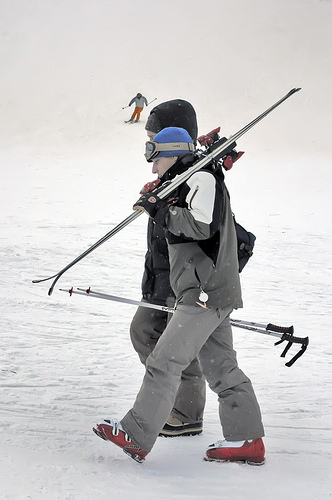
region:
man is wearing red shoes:
[99, 419, 145, 463]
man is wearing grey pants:
[133, 324, 251, 424]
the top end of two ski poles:
[267, 317, 310, 361]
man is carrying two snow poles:
[73, 279, 310, 366]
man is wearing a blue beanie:
[139, 126, 195, 157]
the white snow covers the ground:
[24, 300, 95, 397]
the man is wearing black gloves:
[131, 191, 159, 215]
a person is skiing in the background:
[124, 86, 146, 124]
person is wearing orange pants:
[127, 108, 145, 120]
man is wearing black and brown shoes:
[164, 410, 198, 443]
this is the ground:
[150, 29, 239, 66]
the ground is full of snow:
[19, 133, 63, 185]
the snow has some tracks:
[18, 306, 86, 376]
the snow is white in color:
[25, 152, 88, 182]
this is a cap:
[161, 130, 181, 141]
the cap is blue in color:
[163, 129, 182, 139]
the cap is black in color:
[156, 104, 182, 117]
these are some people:
[54, 85, 330, 464]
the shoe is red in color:
[221, 451, 238, 457]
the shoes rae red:
[98, 415, 265, 479]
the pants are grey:
[148, 329, 255, 421]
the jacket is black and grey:
[162, 191, 243, 296]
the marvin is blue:
[152, 129, 194, 154]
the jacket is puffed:
[141, 228, 160, 290]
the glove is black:
[128, 191, 163, 216]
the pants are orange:
[128, 106, 147, 119]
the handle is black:
[268, 321, 313, 363]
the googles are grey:
[142, 141, 188, 155]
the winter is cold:
[6, 34, 329, 496]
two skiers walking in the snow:
[35, 101, 306, 464]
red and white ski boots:
[199, 439, 272, 467]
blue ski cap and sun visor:
[147, 129, 192, 156]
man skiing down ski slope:
[112, 88, 145, 124]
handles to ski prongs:
[266, 321, 311, 367]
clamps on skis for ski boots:
[196, 125, 226, 150]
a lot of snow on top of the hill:
[3, 2, 330, 82]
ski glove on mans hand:
[125, 191, 163, 218]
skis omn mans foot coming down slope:
[122, 120, 138, 126]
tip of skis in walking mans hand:
[29, 277, 55, 295]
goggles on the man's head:
[141, 139, 199, 161]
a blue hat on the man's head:
[141, 125, 197, 164]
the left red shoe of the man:
[90, 415, 152, 466]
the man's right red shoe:
[199, 430, 275, 464]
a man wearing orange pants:
[116, 88, 157, 126]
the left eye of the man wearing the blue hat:
[153, 157, 160, 165]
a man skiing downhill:
[119, 90, 158, 126]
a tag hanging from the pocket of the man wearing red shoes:
[193, 284, 210, 311]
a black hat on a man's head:
[139, 94, 202, 145]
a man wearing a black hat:
[135, 88, 207, 438]